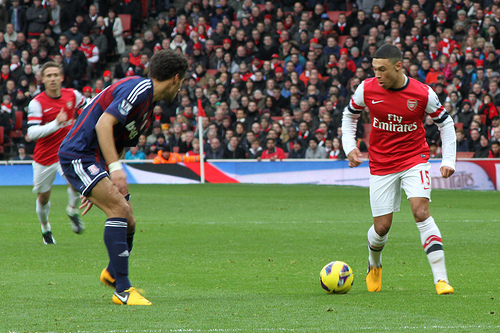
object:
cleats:
[112, 287, 153, 306]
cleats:
[365, 261, 383, 292]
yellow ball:
[319, 261, 355, 295]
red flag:
[198, 99, 206, 117]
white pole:
[198, 116, 205, 184]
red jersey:
[364, 76, 431, 176]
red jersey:
[32, 87, 78, 166]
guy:
[340, 44, 456, 294]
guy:
[56, 49, 188, 307]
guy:
[26, 62, 87, 247]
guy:
[333, 12, 350, 35]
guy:
[307, 51, 316, 60]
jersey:
[54, 75, 154, 162]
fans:
[2, 4, 496, 156]